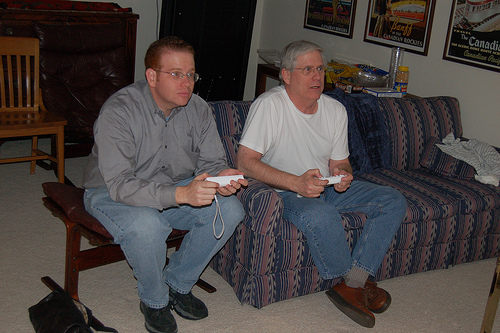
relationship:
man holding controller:
[83, 35, 249, 332] [206, 173, 244, 189]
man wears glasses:
[83, 35, 249, 332] [154, 68, 201, 79]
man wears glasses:
[236, 40, 406, 326] [288, 65, 327, 72]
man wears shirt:
[236, 40, 406, 326] [237, 85, 349, 191]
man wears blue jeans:
[236, 40, 406, 326] [275, 179, 407, 278]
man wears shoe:
[236, 40, 406, 326] [324, 276, 375, 327]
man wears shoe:
[236, 40, 406, 326] [362, 280, 392, 313]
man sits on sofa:
[236, 40, 406, 326] [208, 95, 499, 309]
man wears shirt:
[83, 35, 249, 332] [83, 81, 227, 209]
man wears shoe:
[83, 35, 249, 332] [138, 297, 177, 332]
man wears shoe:
[83, 35, 249, 332] [168, 279, 208, 319]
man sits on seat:
[83, 35, 249, 332] [41, 179, 217, 318]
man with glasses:
[83, 35, 249, 332] [154, 68, 201, 79]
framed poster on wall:
[303, 0, 357, 39] [260, 1, 499, 147]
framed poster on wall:
[361, 0, 438, 57] [260, 1, 499, 147]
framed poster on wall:
[442, 0, 500, 73] [260, 1, 499, 147]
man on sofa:
[236, 40, 406, 326] [208, 95, 499, 309]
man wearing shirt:
[83, 35, 249, 332] [83, 81, 227, 209]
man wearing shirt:
[236, 40, 406, 326] [237, 85, 349, 191]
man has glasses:
[83, 35, 249, 332] [154, 68, 201, 79]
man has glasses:
[236, 40, 406, 326] [288, 65, 327, 72]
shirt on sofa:
[435, 131, 499, 186] [208, 95, 499, 309]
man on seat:
[83, 35, 249, 332] [41, 179, 217, 318]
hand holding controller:
[177, 172, 219, 207] [206, 173, 244, 189]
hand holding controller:
[215, 168, 248, 197] [206, 173, 244, 189]